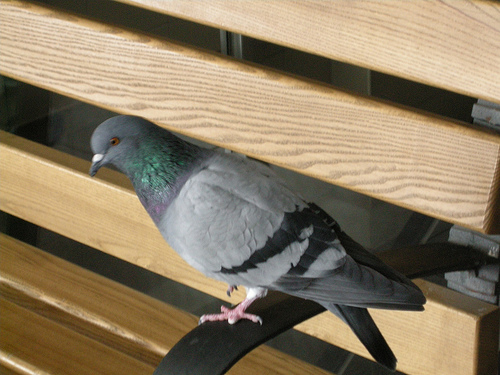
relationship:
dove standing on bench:
[88, 113, 429, 369] [3, 4, 499, 374]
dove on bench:
[88, 113, 429, 369] [3, 4, 499, 374]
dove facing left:
[88, 113, 429, 369] [88, 111, 147, 186]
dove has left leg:
[88, 113, 429, 369] [201, 278, 271, 327]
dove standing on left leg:
[88, 113, 429, 369] [201, 278, 271, 327]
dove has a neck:
[88, 113, 429, 369] [136, 133, 207, 205]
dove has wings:
[88, 113, 429, 369] [223, 161, 426, 370]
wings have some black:
[223, 161, 426, 370] [220, 193, 345, 286]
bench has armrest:
[3, 4, 499, 374] [146, 239, 499, 374]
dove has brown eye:
[88, 113, 429, 369] [109, 133, 121, 148]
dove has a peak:
[88, 113, 429, 369] [90, 152, 104, 177]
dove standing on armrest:
[88, 113, 429, 369] [146, 239, 499, 374]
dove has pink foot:
[88, 113, 429, 369] [199, 305, 263, 328]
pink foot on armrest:
[199, 305, 263, 328] [146, 239, 499, 374]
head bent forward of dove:
[90, 111, 164, 177] [88, 113, 429, 369]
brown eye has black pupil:
[109, 133, 121, 148] [112, 139, 117, 144]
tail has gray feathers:
[325, 299, 402, 365] [146, 137, 424, 369]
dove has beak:
[88, 113, 429, 369] [92, 157, 102, 176]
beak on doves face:
[92, 157, 102, 176] [90, 133, 131, 176]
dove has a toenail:
[88, 113, 429, 369] [255, 315, 264, 325]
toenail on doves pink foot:
[255, 315, 264, 325] [199, 305, 263, 328]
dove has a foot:
[88, 113, 429, 369] [199, 305, 263, 328]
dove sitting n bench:
[88, 113, 429, 369] [3, 4, 499, 374]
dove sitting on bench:
[88, 113, 429, 369] [3, 4, 499, 374]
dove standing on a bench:
[88, 113, 429, 369] [3, 4, 499, 374]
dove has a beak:
[88, 113, 429, 369] [92, 157, 102, 176]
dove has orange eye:
[88, 113, 429, 369] [109, 133, 121, 148]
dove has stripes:
[88, 113, 429, 369] [224, 204, 345, 290]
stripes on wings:
[224, 204, 345, 290] [223, 161, 426, 370]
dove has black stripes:
[88, 113, 429, 369] [224, 204, 345, 290]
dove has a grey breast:
[88, 113, 429, 369] [153, 211, 213, 271]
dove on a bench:
[88, 113, 429, 369] [3, 4, 499, 374]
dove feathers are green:
[88, 113, 429, 369] [138, 138, 189, 191]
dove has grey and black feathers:
[88, 113, 429, 369] [146, 137, 424, 369]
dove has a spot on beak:
[88, 113, 429, 369] [92, 157, 102, 176]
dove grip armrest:
[88, 113, 429, 369] [146, 239, 499, 374]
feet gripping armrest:
[199, 291, 265, 331] [146, 239, 499, 374]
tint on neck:
[122, 138, 212, 210] [136, 133, 207, 205]